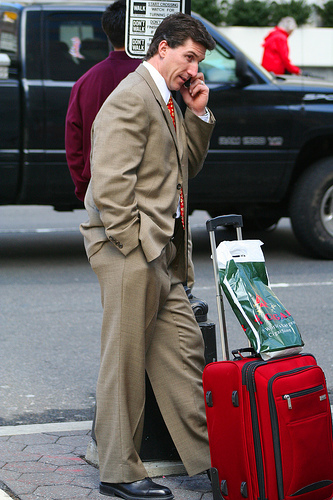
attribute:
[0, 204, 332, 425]
street — paved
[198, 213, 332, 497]
luggage — red, rolling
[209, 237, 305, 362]
shopping bag — plastic, green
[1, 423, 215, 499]
sidewalk — concrete, paved, tiled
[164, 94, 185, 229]
tie — red, white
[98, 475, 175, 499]
right shoe — black, dressy, leather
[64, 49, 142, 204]
shirt — long sleeve, burgundy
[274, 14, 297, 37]
hair — grey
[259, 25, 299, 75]
jacket — red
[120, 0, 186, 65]
crossing sign — white, black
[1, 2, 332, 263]
truck — black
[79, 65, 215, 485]
suit — brown